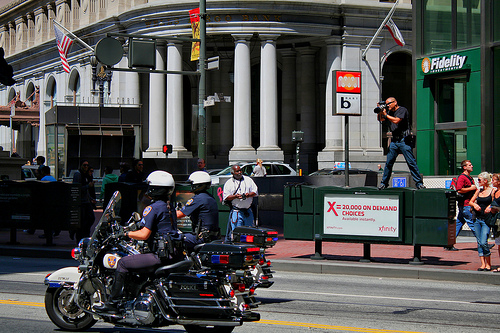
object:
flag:
[53, 24, 74, 73]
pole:
[48, 16, 94, 52]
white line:
[259, 285, 474, 310]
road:
[0, 252, 500, 333]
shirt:
[142, 201, 179, 243]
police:
[176, 170, 218, 250]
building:
[0, 0, 422, 173]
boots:
[92, 270, 127, 314]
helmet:
[143, 170, 175, 200]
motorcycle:
[225, 226, 279, 289]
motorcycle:
[43, 190, 258, 333]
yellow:
[276, 312, 358, 331]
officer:
[176, 170, 222, 244]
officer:
[92, 170, 187, 315]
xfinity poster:
[320, 192, 404, 243]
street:
[279, 235, 466, 305]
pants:
[117, 253, 161, 273]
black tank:
[283, 182, 457, 246]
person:
[443, 160, 494, 251]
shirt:
[455, 171, 477, 205]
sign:
[318, 195, 400, 240]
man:
[373, 97, 427, 190]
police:
[90, 170, 186, 314]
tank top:
[469, 187, 497, 217]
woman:
[467, 164, 497, 271]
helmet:
[185, 171, 212, 193]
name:
[421, 54, 466, 74]